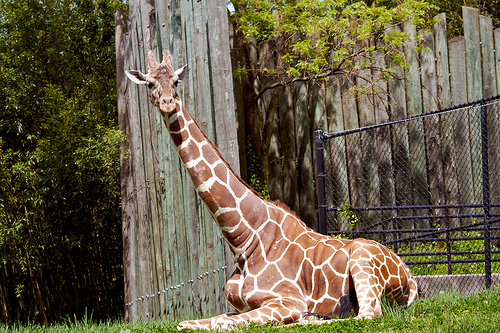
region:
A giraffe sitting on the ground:
[121, 48, 431, 332]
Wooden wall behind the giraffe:
[110, 0, 367, 331]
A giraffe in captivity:
[58, 15, 491, 326]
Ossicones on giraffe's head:
[141, 41, 176, 73]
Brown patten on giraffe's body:
[129, 48, 424, 321]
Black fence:
[277, 78, 497, 266]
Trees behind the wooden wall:
[5, 3, 401, 313]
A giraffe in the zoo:
[124, 41, 435, 331]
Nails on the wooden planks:
[125, 260, 240, 311]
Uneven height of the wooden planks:
[269, 13, 494, 85]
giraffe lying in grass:
[108, 36, 435, 328]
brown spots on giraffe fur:
[254, 227, 319, 290]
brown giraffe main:
[182, 102, 311, 231]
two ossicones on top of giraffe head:
[134, 47, 176, 66]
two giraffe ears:
[114, 59, 191, 83]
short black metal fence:
[301, 90, 498, 303]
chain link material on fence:
[350, 150, 454, 195]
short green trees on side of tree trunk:
[231, 16, 423, 193]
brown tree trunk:
[108, 14, 260, 321]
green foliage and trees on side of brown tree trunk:
[1, 3, 160, 328]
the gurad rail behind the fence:
[326, 204, 498, 239]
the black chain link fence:
[438, 92, 498, 299]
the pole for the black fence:
[312, 125, 337, 232]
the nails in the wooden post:
[120, 245, 220, 315]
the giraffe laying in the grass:
[116, 51, 418, 331]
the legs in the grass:
[182, 298, 403, 332]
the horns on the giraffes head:
[141, 44, 174, 71]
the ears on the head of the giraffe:
[125, 63, 191, 83]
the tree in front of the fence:
[229, 0, 449, 100]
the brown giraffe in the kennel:
[121, 46, 431, 331]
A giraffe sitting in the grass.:
[137, 62, 418, 322]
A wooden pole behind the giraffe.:
[111, 18, 246, 295]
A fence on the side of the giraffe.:
[316, 123, 483, 255]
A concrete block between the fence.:
[421, 269, 494, 292]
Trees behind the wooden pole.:
[22, 37, 140, 282]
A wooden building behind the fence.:
[280, 33, 491, 194]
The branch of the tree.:
[261, 51, 406, 108]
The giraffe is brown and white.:
[146, 55, 307, 302]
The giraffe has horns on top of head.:
[144, 44, 182, 71]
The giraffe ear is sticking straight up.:
[118, 65, 148, 87]